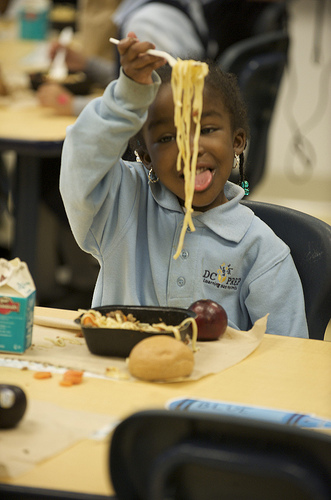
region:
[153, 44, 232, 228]
Noodles at lunpch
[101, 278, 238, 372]
Bread and fruit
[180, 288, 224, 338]
An apple on the table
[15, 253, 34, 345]
Milk carton on the table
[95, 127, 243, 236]
Blue shirt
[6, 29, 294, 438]
Eating lunch at the table in the cafeteria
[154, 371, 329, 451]
A crayon sign with blue written on it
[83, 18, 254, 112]
A girl with a plastic fork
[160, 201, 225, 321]
Buttons on the girls shirt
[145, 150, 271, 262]
Little girl has earings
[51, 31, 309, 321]
Little girl eating her lunch.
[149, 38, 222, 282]
A spoonful of noodles.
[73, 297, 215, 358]
A black container of noodles.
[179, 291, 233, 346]
Apple next to a bowl of noodles.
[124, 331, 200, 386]
A roll on a paper towel.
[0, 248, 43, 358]
Blue and white carton of milk.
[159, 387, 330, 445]
A blue crayon.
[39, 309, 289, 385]
Brown paper towel on the table.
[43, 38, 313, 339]
Little girl wearing a blue shirt.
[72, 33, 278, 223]
Young girl wearing pretty hoop earrings.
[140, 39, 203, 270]
girl holding pasta in the air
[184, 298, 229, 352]
apple on a napkin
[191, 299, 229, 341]
apple is dark red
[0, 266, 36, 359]
carton of milk is blue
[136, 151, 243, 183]
girl has gold earrings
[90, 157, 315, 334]
girl has a blue shirt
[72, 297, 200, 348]
pasta in a black dish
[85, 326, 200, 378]
dinner roll by the black dish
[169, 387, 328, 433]
blue crayon on table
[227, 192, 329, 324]
girl is sitting in a chair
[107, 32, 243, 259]
a little girl picking up pasta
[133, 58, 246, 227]
the girl's tongue is sticking out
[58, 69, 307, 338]
the child is wearing a long sleeved shirt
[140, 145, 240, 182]
the child has earrings on her ears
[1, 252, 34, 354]
a carton of milk is on the table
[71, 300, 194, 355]
a plate of pasta is on the table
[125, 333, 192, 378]
a roll is next to the pasta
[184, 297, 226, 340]
an apple is on the table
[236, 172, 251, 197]
the little girl has beads in her hair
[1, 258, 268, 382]
the lunch is on a piece of paper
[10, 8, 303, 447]
a school cafeteria scene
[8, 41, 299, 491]
a girl eating lunch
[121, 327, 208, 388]
a golden dinner roll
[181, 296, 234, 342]
a dark red fruit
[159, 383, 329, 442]
a picture of a crayon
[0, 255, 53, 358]
a blue carton of milk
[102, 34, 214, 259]
a fork full of spaghetti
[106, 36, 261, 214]
a girl with gold earrings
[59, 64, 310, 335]
a light blue pullover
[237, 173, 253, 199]
two pale blue beads